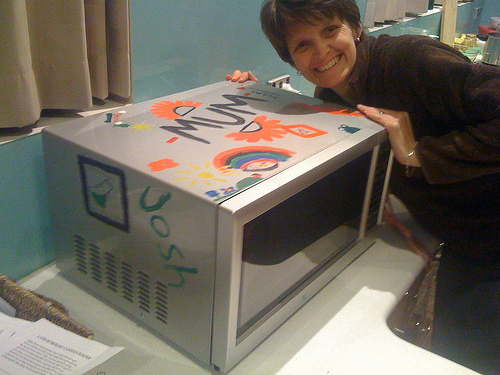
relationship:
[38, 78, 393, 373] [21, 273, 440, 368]
microwave on table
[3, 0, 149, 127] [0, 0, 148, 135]
curtain on window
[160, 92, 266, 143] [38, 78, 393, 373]
mum on top of microwave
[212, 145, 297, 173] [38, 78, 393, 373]
rainbow on top of microwave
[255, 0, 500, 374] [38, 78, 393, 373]
woman holding microwave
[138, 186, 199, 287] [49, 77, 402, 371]
josh on side of micowave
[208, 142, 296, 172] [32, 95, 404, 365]
rainbow painted on top of microwave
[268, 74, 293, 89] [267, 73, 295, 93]
outlet plugged into outlet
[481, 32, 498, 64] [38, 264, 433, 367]
crockpot on counter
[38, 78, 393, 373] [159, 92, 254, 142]
microwave with art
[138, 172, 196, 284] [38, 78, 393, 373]
art on microwave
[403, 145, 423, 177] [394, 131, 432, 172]
bracelet on wrist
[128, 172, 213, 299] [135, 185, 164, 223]
josh written in paint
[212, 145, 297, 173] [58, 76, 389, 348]
rainbow painted on microwave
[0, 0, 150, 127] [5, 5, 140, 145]
curtain over window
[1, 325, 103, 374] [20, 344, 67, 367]
paper with text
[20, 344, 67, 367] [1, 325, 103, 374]
text on paper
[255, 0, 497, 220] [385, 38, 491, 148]
woman in sweater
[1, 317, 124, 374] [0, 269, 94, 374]
paper in basket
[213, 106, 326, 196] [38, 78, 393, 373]
drawings on microwave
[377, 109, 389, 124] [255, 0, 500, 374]
ring on woman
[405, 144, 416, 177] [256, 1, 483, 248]
bracelet on woman